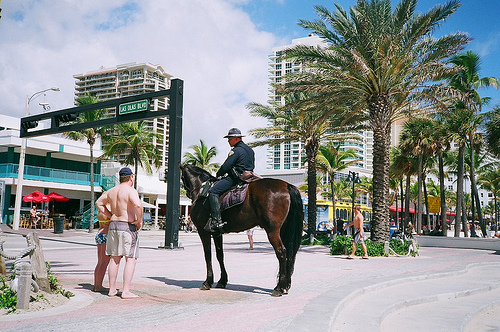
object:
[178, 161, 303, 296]
horse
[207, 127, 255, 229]
officer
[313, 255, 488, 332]
street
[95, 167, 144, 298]
man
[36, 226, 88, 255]
road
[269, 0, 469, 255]
tree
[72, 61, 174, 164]
building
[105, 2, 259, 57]
sky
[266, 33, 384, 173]
building